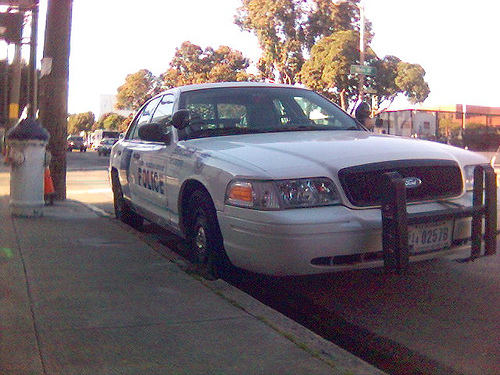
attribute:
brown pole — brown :
[22, 2, 90, 196]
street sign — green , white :
[344, 65, 378, 74]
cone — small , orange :
[38, 169, 62, 199]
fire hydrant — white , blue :
[12, 114, 52, 225]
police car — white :
[106, 81, 497, 288]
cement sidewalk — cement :
[0, 201, 350, 365]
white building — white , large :
[363, 100, 498, 146]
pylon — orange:
[42, 169, 56, 200]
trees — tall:
[242, 0, 356, 86]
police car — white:
[124, 90, 404, 252]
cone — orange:
[42, 161, 56, 201]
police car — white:
[125, 85, 477, 272]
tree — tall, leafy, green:
[241, 1, 411, 101]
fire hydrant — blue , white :
[7, 112, 52, 214]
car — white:
[104, 89, 482, 278]